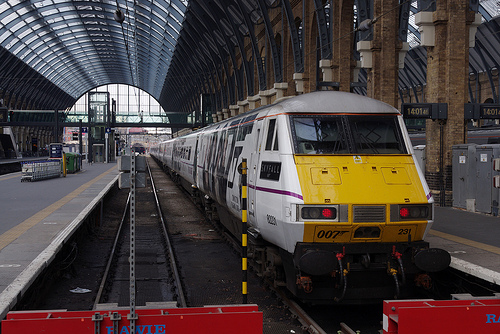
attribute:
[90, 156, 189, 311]
tracks — with no train, empty, straight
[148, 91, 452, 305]
train — yellow, white, long, metro type, running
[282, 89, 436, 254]
front — yellow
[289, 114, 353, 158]
window — square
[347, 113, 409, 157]
window — square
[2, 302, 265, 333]
bumper — in foreground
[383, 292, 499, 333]
bumper — red, in foreground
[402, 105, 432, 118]
sign — 1401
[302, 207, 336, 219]
light — red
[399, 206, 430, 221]
light — red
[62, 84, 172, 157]
outside — daylight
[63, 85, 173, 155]
opening — circular, at the end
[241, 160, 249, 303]
pole — black, yellow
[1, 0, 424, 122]
ceiling — arched, high domed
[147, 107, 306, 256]
side — white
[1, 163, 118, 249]
stripe — yellow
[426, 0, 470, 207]
pillar — brick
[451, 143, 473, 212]
electric box — grey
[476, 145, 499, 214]
electric box — grey